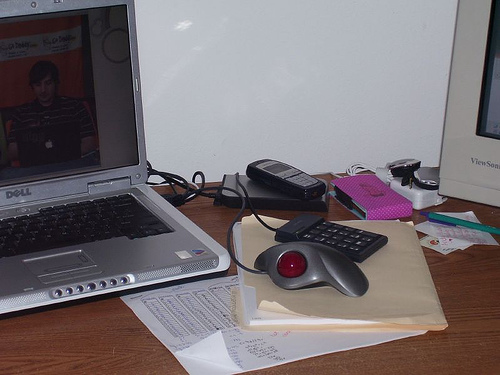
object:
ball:
[276, 250, 309, 281]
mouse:
[251, 241, 369, 299]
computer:
[0, 0, 235, 318]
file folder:
[230, 212, 449, 334]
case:
[327, 171, 415, 221]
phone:
[248, 155, 320, 204]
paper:
[120, 269, 431, 374]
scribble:
[237, 332, 284, 361]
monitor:
[0, 0, 152, 208]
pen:
[416, 209, 499, 234]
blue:
[420, 211, 428, 217]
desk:
[0, 165, 499, 372]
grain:
[48, 329, 102, 366]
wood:
[0, 164, 500, 375]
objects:
[249, 211, 387, 297]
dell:
[2, 183, 40, 202]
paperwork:
[116, 206, 499, 374]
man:
[0, 61, 96, 164]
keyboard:
[0, 194, 174, 257]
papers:
[409, 209, 499, 256]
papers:
[234, 221, 388, 327]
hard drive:
[213, 173, 331, 212]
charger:
[389, 175, 449, 210]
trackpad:
[22, 249, 105, 284]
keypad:
[273, 212, 390, 264]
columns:
[141, 283, 240, 340]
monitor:
[431, 1, 500, 215]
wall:
[127, 0, 459, 186]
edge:
[170, 328, 252, 373]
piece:
[116, 273, 430, 371]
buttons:
[54, 289, 64, 297]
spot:
[174, 19, 192, 34]